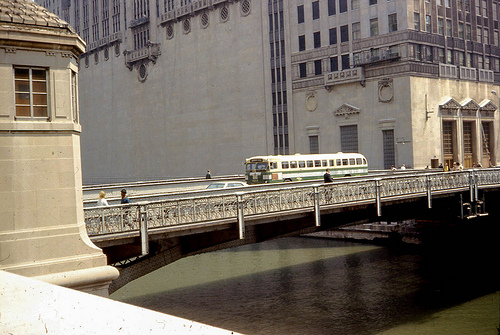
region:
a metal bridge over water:
[72, 154, 489, 276]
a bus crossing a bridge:
[222, 140, 369, 194]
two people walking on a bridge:
[88, 192, 138, 229]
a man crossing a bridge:
[313, 165, 341, 194]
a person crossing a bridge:
[188, 157, 221, 201]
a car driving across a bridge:
[183, 171, 261, 223]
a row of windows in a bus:
[271, 153, 368, 173]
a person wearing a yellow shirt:
[438, 159, 454, 180]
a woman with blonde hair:
[93, 188, 110, 202]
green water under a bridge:
[204, 237, 366, 333]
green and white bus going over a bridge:
[243, 151, 369, 186]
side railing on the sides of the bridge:
[84, 168, 499, 239]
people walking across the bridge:
[94, 186, 135, 230]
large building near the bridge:
[55, 2, 495, 189]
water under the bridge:
[108, 225, 499, 334]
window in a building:
[8, 61, 55, 121]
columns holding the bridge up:
[130, 175, 497, 260]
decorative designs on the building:
[298, 64, 396, 117]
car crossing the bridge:
[200, 178, 242, 191]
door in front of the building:
[442, 110, 498, 172]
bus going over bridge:
[243, 146, 379, 178]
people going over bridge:
[93, 180, 135, 205]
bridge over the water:
[94, 165, 499, 236]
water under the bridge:
[179, 266, 475, 322]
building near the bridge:
[96, 9, 498, 154]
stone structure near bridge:
[3, 10, 126, 288]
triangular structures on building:
[429, 97, 499, 114]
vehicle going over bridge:
[206, 175, 251, 193]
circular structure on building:
[373, 84, 401, 106]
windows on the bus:
[278, 156, 365, 163]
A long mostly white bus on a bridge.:
[243, 152, 368, 185]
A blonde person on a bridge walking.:
[95, 188, 108, 210]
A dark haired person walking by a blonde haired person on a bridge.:
[116, 187, 135, 230]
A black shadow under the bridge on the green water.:
[118, 247, 498, 334]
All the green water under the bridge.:
[112, 235, 498, 333]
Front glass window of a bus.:
[243, 160, 268, 173]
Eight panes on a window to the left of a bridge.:
[9, 63, 50, 121]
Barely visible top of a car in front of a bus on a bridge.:
[206, 179, 248, 191]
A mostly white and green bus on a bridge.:
[243, 151, 368, 185]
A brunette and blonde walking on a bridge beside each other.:
[96, 186, 133, 230]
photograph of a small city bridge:
[28, 13, 483, 325]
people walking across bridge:
[95, 183, 137, 229]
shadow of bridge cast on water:
[98, 244, 498, 327]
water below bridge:
[67, 210, 484, 333]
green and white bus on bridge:
[244, 138, 373, 189]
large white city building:
[90, 0, 497, 175]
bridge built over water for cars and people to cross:
[85, 120, 490, 274]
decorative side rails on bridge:
[94, 168, 494, 237]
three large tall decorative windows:
[436, 87, 498, 170]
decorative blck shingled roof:
[1, 2, 70, 29]